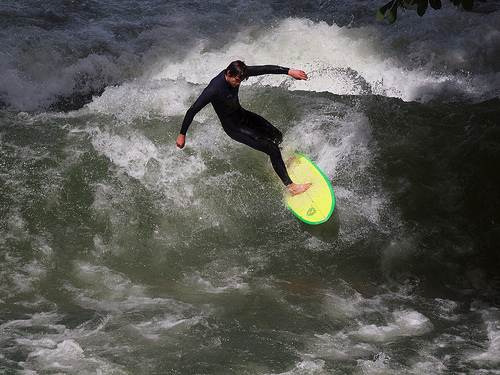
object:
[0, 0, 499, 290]
waves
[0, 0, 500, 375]
ocean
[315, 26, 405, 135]
sandwich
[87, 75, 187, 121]
cap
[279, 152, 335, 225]
green stripe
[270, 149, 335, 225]
board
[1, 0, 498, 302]
tall wave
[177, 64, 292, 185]
black suit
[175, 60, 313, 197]
man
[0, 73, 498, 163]
curl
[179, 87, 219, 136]
arms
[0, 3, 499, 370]
water